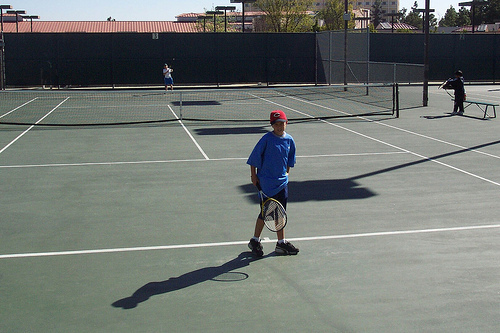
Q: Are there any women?
A: No, there are no women.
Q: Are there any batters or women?
A: No, there are no women or batters.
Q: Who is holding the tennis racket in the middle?
A: The boy is holding the racket.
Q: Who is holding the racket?
A: The boy is holding the racket.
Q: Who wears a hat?
A: The boy wears a hat.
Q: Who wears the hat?
A: The boy wears a hat.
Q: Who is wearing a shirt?
A: The boy is wearing a shirt.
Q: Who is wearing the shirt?
A: The boy is wearing a shirt.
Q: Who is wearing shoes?
A: The boy is wearing shoes.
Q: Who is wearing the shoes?
A: The boy is wearing shoes.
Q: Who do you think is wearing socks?
A: The boy is wearing socks.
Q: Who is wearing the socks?
A: The boy is wearing socks.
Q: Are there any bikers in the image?
A: No, there are no bikers.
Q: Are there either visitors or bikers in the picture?
A: No, there are no bikers or visitors.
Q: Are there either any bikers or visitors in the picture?
A: No, there are no bikers or visitors.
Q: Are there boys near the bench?
A: Yes, there is a boy near the bench.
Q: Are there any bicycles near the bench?
A: No, there is a boy near the bench.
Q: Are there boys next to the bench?
A: Yes, there is a boy next to the bench.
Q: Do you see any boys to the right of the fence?
A: Yes, there is a boy to the right of the fence.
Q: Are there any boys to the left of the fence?
A: No, the boy is to the right of the fence.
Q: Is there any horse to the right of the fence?
A: No, there is a boy to the right of the fence.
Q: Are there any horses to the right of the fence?
A: No, there is a boy to the right of the fence.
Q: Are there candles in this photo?
A: No, there are no candles.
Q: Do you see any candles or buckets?
A: No, there are no candles or buckets.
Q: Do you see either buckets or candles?
A: No, there are no candles or buckets.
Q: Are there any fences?
A: Yes, there is a fence.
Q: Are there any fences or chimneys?
A: Yes, there is a fence.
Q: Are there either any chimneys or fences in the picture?
A: Yes, there is a fence.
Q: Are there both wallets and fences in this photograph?
A: No, there is a fence but no wallets.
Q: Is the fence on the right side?
A: Yes, the fence is on the right of the image.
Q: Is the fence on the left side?
A: No, the fence is on the right of the image.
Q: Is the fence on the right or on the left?
A: The fence is on the right of the image.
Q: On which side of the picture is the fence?
A: The fence is on the right of the image.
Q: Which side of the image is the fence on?
A: The fence is on the right of the image.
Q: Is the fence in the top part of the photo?
A: Yes, the fence is in the top of the image.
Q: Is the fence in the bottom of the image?
A: No, the fence is in the top of the image.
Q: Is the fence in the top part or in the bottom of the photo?
A: The fence is in the top of the image.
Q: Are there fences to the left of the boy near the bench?
A: Yes, there is a fence to the left of the boy.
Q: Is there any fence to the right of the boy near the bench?
A: No, the fence is to the left of the boy.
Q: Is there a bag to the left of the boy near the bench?
A: No, there is a fence to the left of the boy.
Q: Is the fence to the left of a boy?
A: Yes, the fence is to the left of a boy.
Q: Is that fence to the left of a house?
A: No, the fence is to the left of a boy.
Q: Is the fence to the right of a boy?
A: No, the fence is to the left of a boy.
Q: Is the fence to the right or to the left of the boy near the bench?
A: The fence is to the left of the boy.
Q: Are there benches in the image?
A: Yes, there is a bench.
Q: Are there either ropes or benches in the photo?
A: Yes, there is a bench.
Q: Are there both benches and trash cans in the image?
A: No, there is a bench but no trash cans.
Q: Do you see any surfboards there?
A: No, there are no surfboards.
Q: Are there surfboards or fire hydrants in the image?
A: No, there are no surfboards or fire hydrants.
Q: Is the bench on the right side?
A: Yes, the bench is on the right of the image.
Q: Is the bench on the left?
A: No, the bench is on the right of the image.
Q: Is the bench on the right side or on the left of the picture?
A: The bench is on the right of the image.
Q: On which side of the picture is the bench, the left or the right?
A: The bench is on the right of the image.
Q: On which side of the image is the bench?
A: The bench is on the right of the image.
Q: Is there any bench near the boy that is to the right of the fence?
A: Yes, there is a bench near the boy.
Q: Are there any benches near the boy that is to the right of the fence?
A: Yes, there is a bench near the boy.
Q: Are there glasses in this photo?
A: No, there are no glasses.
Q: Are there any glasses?
A: No, there are no glasses.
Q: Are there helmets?
A: No, there are no helmets.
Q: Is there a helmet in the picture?
A: No, there are no helmets.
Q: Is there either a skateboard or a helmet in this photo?
A: No, there are no helmets or skateboards.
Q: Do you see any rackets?
A: Yes, there is a racket.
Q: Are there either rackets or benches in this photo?
A: Yes, there is a racket.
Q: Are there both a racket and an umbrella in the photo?
A: No, there is a racket but no umbrellas.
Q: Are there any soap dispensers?
A: No, there are no soap dispensers.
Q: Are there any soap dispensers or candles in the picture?
A: No, there are no soap dispensers or candles.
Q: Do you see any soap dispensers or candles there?
A: No, there are no soap dispensers or candles.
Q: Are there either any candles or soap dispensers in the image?
A: No, there are no soap dispensers or candles.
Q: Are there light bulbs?
A: No, there are no light bulbs.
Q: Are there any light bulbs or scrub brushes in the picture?
A: No, there are no light bulbs or scrub brushes.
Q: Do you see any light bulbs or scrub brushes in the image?
A: No, there are no light bulbs or scrub brushes.